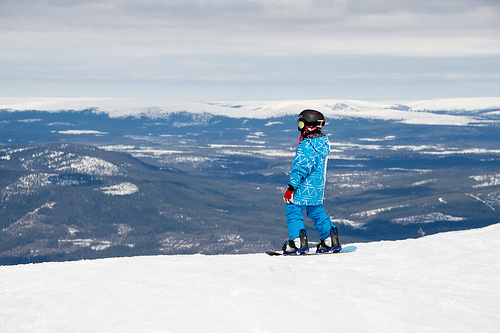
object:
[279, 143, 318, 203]
arm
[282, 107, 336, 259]
skier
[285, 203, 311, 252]
legs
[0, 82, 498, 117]
snow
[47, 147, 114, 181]
snow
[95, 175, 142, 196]
snow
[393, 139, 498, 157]
snow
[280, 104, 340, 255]
boy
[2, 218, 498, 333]
ground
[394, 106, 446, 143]
ground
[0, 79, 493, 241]
valley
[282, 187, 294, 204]
glove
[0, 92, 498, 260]
mountains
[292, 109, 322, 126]
head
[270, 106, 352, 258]
small snowboader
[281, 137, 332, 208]
blue clothes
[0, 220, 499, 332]
white snow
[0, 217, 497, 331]
mountain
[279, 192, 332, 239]
pants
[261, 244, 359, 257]
snowboard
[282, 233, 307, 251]
boot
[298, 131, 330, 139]
scarf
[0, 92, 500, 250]
dressed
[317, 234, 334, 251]
boot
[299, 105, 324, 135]
helmet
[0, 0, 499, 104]
sky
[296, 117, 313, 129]
goggles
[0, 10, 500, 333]
view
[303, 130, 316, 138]
strap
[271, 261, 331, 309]
part